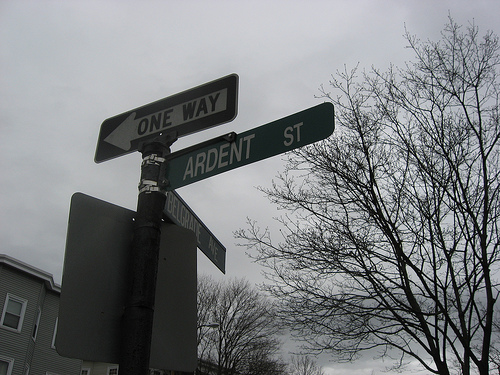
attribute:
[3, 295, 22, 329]
window — rectangular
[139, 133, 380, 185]
sign — green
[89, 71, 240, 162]
direction post — black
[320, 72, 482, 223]
tree — barren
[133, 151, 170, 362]
pole — thick, metal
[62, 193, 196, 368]
road sign — rectangle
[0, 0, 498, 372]
cloudy sky — gray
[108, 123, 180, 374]
pole — black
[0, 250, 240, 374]
building — gray, white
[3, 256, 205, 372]
houses — light, colored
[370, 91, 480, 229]
tree — branchy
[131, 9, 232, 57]
sky — grey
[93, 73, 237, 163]
sign — green, white, black